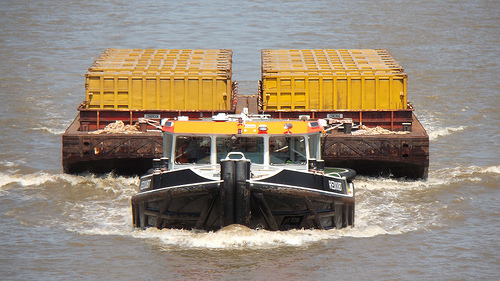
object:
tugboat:
[61, 44, 428, 235]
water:
[3, 0, 500, 281]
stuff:
[84, 38, 416, 123]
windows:
[172, 131, 308, 164]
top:
[163, 118, 324, 136]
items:
[59, 111, 428, 139]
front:
[62, 111, 434, 234]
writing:
[132, 172, 349, 191]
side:
[321, 172, 354, 220]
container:
[84, 40, 240, 108]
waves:
[132, 227, 366, 252]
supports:
[77, 103, 410, 128]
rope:
[90, 120, 146, 137]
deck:
[61, 115, 431, 172]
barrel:
[340, 118, 354, 134]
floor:
[332, 121, 415, 132]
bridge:
[233, 86, 260, 113]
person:
[181, 132, 210, 168]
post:
[241, 97, 258, 114]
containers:
[260, 49, 408, 118]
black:
[337, 120, 359, 136]